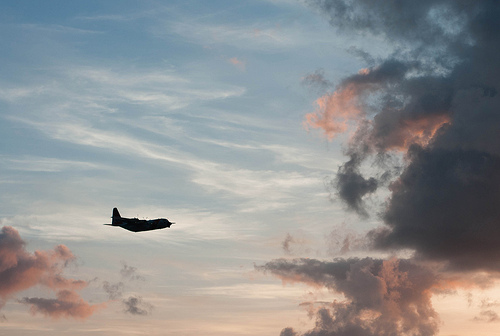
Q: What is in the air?
A: Airplane.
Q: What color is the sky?
A: Blue.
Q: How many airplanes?
A: One.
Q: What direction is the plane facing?
A: Right.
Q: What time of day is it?
A: Evening.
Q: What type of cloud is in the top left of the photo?
A: Stratus.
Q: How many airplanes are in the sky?
A: 1.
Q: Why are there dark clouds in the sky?
A: Thunderstorm about to occur.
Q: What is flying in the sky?
A: An airplane.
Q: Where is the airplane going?
A: Another country.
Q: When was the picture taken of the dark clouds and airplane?
A: Late evening.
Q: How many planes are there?
A: 1.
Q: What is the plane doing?
A: Flying.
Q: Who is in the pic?
A: No one.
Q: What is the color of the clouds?
A: White.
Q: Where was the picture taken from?
A: In the sky.